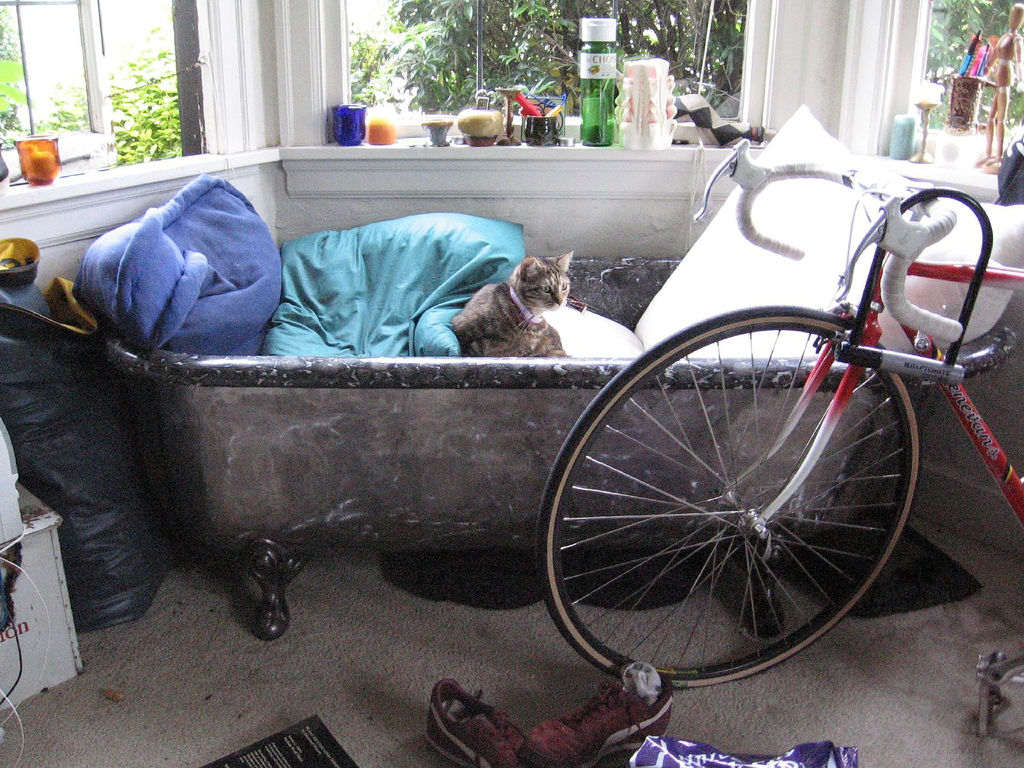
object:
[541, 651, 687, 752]
shoes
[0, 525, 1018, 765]
ground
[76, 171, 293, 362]
pillow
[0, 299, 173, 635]
bag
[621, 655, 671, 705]
sock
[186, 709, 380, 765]
book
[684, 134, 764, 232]
brakes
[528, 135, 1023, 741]
bike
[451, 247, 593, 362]
cat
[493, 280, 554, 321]
collar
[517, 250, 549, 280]
ear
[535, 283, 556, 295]
eyes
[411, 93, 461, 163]
object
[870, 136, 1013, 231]
windowsill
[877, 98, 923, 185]
object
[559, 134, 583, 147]
object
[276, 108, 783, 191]
windowsill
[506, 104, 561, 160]
object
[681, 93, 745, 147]
object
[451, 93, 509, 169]
object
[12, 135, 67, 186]
object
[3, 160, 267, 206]
windowsill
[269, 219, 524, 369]
pillow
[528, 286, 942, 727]
tire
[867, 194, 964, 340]
handlebars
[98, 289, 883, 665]
claw tub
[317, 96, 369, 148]
cup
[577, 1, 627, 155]
bottle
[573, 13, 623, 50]
cap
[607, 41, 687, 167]
decorative candle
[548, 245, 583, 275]
ear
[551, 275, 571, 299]
eye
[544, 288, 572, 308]
nose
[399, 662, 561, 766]
shoe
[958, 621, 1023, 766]
shoe